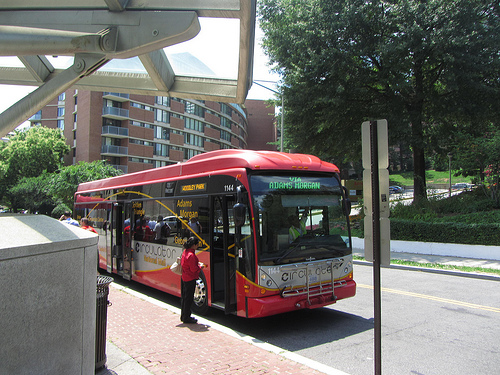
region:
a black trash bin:
[93, 275, 105, 369]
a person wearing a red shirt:
[178, 230, 198, 320]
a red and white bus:
[72, 145, 349, 317]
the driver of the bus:
[287, 207, 304, 235]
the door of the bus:
[211, 199, 233, 302]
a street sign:
[356, 113, 381, 373]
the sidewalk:
[109, 288, 204, 370]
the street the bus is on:
[287, 243, 474, 366]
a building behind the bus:
[58, 88, 250, 153]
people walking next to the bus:
[62, 212, 97, 247]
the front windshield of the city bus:
[248, 172, 351, 261]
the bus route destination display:
[255, 172, 335, 191]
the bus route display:
[178, 182, 207, 192]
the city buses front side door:
[212, 194, 238, 313]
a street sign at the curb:
[361, 117, 389, 374]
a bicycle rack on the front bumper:
[281, 257, 346, 309]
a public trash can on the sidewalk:
[92, 271, 112, 372]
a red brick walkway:
[133, 323, 270, 374]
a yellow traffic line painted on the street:
[383, 284, 498, 319]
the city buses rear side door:
[103, 202, 128, 277]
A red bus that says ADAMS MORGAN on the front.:
[73, 147, 357, 319]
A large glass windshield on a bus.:
[247, 174, 352, 259]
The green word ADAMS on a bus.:
[268, 180, 293, 191]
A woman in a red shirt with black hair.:
[178, 233, 208, 326]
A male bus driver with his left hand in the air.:
[288, 199, 312, 244]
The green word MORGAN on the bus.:
[293, 180, 323, 191]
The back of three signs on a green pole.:
[359, 119, 394, 374]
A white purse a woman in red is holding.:
[171, 255, 187, 277]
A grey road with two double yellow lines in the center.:
[261, 259, 498, 373]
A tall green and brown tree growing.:
[257, 0, 497, 211]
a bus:
[82, 157, 339, 239]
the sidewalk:
[166, 340, 237, 372]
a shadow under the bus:
[283, 317, 335, 341]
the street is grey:
[416, 313, 475, 368]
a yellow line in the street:
[457, 297, 489, 309]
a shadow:
[35, 215, 62, 240]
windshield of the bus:
[253, 194, 345, 255]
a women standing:
[175, 234, 210, 325]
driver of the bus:
[288, 214, 306, 232]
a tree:
[405, 76, 438, 202]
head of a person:
[175, 229, 209, 257]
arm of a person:
[186, 261, 208, 273]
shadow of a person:
[197, 312, 221, 346]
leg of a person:
[172, 275, 200, 333]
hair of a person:
[172, 236, 197, 251]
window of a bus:
[237, 175, 374, 272]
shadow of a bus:
[276, 313, 400, 373]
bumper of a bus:
[263, 245, 357, 316]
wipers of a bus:
[296, 221, 358, 275]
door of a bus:
[176, 175, 241, 336]